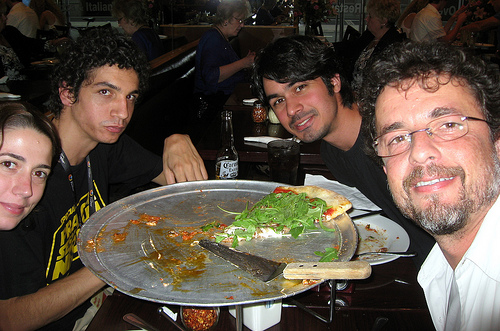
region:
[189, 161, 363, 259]
A piece of basil pizza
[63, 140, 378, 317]
A pizza pan with one slice left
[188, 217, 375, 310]
A pizza serving tool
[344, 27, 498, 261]
A man with curly hair and glasses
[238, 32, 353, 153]
A man with dark hair and eyes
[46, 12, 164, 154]
A man with curly dark hair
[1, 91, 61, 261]
A woman's face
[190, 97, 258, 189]
A beer bottle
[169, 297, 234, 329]
A jar of hot pepper flakes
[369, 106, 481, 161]
A man's glasses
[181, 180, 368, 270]
pizza with green on it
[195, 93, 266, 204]
glass bottle of beer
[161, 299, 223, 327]
crushed red pepper jar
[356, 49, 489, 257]
man with glasses taking photo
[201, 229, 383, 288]
Pizza cutter on tray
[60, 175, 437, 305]
Metal pizza tray on stand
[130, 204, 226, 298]
Pizza sauce on tray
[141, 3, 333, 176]
people eating in back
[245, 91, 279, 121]
Red pepper shaker on table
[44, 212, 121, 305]
yellow writing on shirt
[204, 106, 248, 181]
a corona beer bottle on the table.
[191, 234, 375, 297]
a spatula is on the pizza pan.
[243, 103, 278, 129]
spices are on the table.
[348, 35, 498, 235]
a man is wearing glasses.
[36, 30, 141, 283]
a man is wearing a black and yellow tea shirt.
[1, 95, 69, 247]
a woman is sitting next to the man.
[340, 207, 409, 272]
the white plate is empty.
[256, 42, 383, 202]
a man is wearing a black tea shirt.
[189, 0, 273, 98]
a woman is eating.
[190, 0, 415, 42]
two women are talking.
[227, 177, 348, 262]
pizza with lettuce on top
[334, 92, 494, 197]
person wearing glasses and smiling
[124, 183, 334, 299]
one piece of pizza on silver tray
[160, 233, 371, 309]
a silver pizza server withn wooden handle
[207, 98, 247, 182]
a bottle of corona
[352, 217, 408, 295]
white plate with silverware on it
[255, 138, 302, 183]
a cuo of watre with ice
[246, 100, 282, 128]
parmesan cheese and red peppers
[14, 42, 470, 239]
four people and a pizza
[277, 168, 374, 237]
white napkins on table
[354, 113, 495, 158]
The man is wearing glasses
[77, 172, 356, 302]
The plate is metal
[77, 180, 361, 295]
The plate is round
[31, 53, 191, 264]
The boy is wearing a black and yellow shirt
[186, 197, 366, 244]
A pizza slice is on top of the plate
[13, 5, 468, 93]
People are eating in booths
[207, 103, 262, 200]
A clear beer bottle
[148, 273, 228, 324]
A clear shaker with pepper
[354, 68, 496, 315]
The man is wearing a white shirt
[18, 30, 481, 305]
The people are sitting down